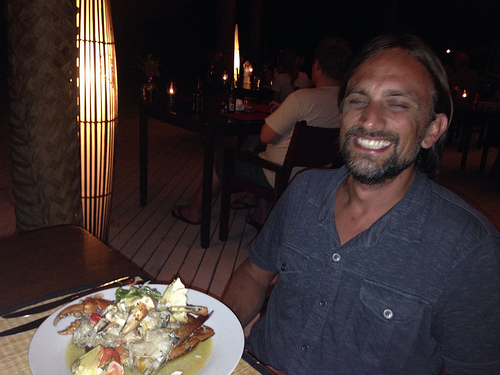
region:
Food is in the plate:
[22, 254, 257, 374]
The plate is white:
[24, 272, 269, 374]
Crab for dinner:
[45, 287, 143, 341]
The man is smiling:
[320, 30, 455, 200]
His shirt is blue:
[226, 135, 491, 374]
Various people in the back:
[123, 2, 499, 191]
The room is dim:
[122, 0, 499, 260]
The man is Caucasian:
[220, 33, 455, 251]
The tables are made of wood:
[112, 36, 499, 236]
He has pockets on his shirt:
[265, 217, 458, 362]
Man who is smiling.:
[279, 32, 493, 236]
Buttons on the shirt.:
[321, 224, 345, 308]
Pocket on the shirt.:
[341, 250, 425, 342]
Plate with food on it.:
[39, 262, 118, 351]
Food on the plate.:
[31, 276, 176, 371]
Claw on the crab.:
[43, 272, 173, 353]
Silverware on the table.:
[13, 270, 200, 347]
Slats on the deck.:
[101, 170, 216, 300]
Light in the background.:
[196, 28, 311, 120]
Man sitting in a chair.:
[188, 77, 425, 264]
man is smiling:
[329, 41, 464, 192]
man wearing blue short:
[240, 48, 482, 365]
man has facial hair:
[310, 40, 467, 221]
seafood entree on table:
[17, 274, 263, 374]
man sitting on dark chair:
[232, 49, 351, 193]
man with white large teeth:
[297, 34, 466, 206]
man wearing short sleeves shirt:
[232, 139, 488, 353]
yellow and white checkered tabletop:
[2, 256, 285, 373]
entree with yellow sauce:
[24, 274, 258, 373]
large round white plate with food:
[20, 269, 262, 374]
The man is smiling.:
[317, 25, 461, 182]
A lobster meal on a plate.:
[21, 272, 251, 374]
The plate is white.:
[19, 277, 245, 372]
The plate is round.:
[12, 262, 251, 374]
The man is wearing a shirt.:
[223, 27, 499, 372]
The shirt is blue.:
[223, 164, 498, 373]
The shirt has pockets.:
[225, 143, 499, 373]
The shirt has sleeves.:
[224, 163, 499, 373]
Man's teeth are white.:
[328, 38, 459, 183]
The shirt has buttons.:
[239, 157, 498, 373]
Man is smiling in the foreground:
[344, 123, 401, 162]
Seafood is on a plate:
[23, 263, 247, 373]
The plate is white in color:
[23, 268, 252, 374]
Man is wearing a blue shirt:
[233, 161, 495, 374]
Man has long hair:
[319, 22, 475, 185]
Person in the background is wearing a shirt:
[243, 83, 340, 197]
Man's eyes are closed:
[337, 83, 430, 120]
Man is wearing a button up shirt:
[220, 163, 499, 373]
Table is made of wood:
[5, 223, 147, 301]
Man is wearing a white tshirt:
[254, 78, 342, 195]